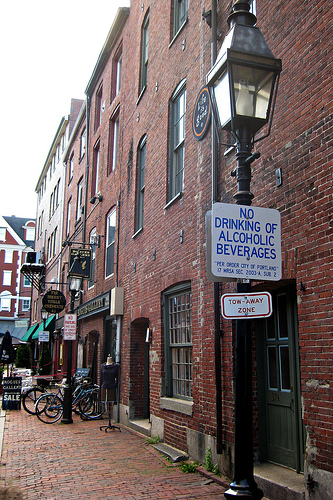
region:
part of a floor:
[121, 468, 137, 485]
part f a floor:
[95, 452, 116, 480]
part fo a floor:
[102, 449, 118, 466]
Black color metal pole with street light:
[176, 6, 283, 496]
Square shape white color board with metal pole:
[208, 201, 286, 283]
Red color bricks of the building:
[288, 127, 323, 207]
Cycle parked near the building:
[25, 383, 105, 430]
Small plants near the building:
[147, 434, 218, 484]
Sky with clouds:
[10, 74, 51, 109]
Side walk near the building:
[17, 435, 92, 489]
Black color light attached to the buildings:
[52, 196, 104, 250]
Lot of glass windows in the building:
[70, 51, 188, 216]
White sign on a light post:
[209, 201, 283, 283]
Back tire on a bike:
[35, 393, 63, 423]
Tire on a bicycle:
[22, 387, 47, 414]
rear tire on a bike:
[33, 392, 61, 424]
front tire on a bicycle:
[78, 388, 104, 417]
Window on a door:
[265, 344, 278, 390]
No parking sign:
[63, 314, 75, 340]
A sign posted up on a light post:
[38, 331, 50, 341]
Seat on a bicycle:
[54, 382, 65, 389]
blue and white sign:
[203, 197, 287, 284]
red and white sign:
[216, 289, 277, 322]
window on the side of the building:
[95, 202, 129, 284]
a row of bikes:
[23, 366, 104, 430]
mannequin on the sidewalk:
[91, 349, 130, 436]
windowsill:
[154, 395, 197, 417]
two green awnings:
[15, 320, 64, 342]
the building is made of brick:
[54, 1, 332, 499]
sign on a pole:
[59, 314, 83, 347]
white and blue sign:
[208, 197, 291, 286]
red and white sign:
[217, 286, 277, 326]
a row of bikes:
[17, 363, 107, 428]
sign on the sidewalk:
[0, 374, 25, 416]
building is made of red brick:
[60, 3, 332, 494]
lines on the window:
[162, 290, 194, 397]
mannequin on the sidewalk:
[94, 352, 125, 437]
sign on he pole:
[55, 308, 83, 346]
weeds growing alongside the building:
[201, 443, 226, 475]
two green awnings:
[19, 317, 55, 343]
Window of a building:
[161, 81, 189, 211]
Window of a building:
[158, 287, 196, 402]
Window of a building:
[159, 283, 199, 408]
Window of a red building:
[156, 280, 197, 409]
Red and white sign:
[217, 288, 272, 321]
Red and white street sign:
[218, 287, 272, 325]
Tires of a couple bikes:
[20, 387, 62, 423]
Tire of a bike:
[33, 394, 63, 425]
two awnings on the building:
[21, 312, 57, 342]